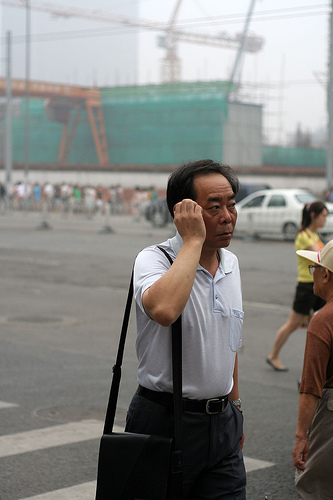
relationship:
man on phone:
[121, 161, 245, 498] [174, 206, 199, 224]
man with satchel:
[121, 161, 245, 498] [95, 245, 198, 499]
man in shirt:
[121, 161, 245, 498] [133, 228, 245, 400]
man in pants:
[121, 161, 245, 498] [124, 388, 246, 499]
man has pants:
[121, 161, 245, 498] [124, 388, 246, 499]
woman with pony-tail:
[263, 202, 331, 374] [301, 202, 311, 234]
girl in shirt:
[263, 202, 331, 374] [295, 230, 328, 284]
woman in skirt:
[263, 202, 331, 374] [290, 278, 332, 317]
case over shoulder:
[95, 245, 198, 499] [135, 244, 170, 284]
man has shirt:
[291, 241, 331, 495] [298, 301, 332, 399]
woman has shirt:
[263, 202, 331, 374] [295, 230, 328, 284]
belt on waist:
[137, 385, 229, 414] [137, 368, 235, 417]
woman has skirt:
[263, 202, 331, 374] [290, 278, 332, 317]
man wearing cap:
[291, 241, 331, 495] [287, 242, 332, 271]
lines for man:
[4, 400, 273, 498] [121, 156, 245, 499]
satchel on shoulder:
[95, 245, 198, 499] [135, 244, 170, 284]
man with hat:
[291, 241, 331, 495] [287, 242, 332, 271]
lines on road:
[4, 400, 273, 498] [1, 224, 331, 499]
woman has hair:
[263, 202, 331, 374] [299, 199, 326, 232]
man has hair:
[121, 161, 245, 498] [166, 159, 240, 216]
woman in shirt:
[263, 202, 331, 374] [295, 230, 328, 284]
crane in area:
[8, 2, 265, 98] [4, 5, 332, 168]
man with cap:
[291, 241, 331, 495] [287, 242, 332, 271]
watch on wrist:
[232, 400, 241, 408] [228, 396, 244, 408]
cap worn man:
[287, 242, 332, 271] [291, 241, 331, 495]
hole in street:
[11, 315, 61, 325] [1, 224, 331, 499]